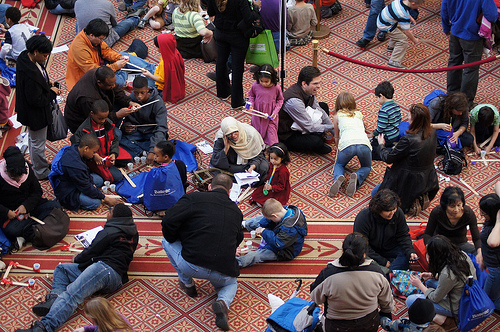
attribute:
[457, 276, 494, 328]
backpack — blue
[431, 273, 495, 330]
backpack — blue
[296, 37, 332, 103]
barrier — gold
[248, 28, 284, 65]
bag — large, green, shopping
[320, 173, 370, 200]
shoes. — girls, bottom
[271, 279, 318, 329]
stroller — blue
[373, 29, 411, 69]
pants — khaki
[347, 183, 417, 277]
woman — five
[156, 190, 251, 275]
shirt — blue, white, black, striped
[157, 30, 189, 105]
red jacket — hanging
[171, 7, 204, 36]
striped shirt — white, green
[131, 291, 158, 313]
ground — part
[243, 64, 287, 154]
girl — little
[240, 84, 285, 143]
dress — pink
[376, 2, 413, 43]
shirt — white, blue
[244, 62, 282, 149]
girl — little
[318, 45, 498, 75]
rope — red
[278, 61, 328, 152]
man — sitting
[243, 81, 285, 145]
dress — part, purple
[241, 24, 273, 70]
bag — green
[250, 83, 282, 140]
dress — pink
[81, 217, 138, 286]
jacket — black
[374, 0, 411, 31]
shirt — striped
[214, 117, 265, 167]
wrap — white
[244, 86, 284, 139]
dress — pink